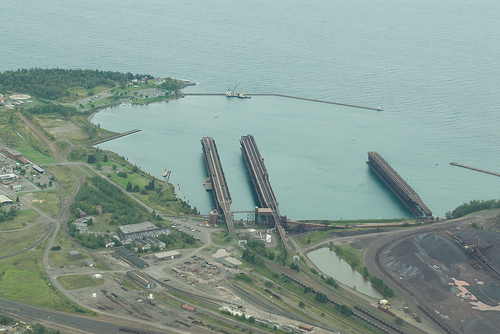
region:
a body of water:
[324, 156, 365, 190]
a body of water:
[286, 127, 311, 162]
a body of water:
[326, 41, 356, 68]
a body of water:
[255, 37, 283, 62]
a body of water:
[164, 22, 196, 53]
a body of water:
[122, 26, 141, 51]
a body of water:
[87, 28, 109, 48]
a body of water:
[50, 20, 78, 45]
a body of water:
[10, 25, 47, 57]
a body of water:
[463, 66, 493, 106]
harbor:
[190, 122, 281, 205]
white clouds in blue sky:
[415, 11, 446, 35]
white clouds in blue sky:
[294, 26, 325, 40]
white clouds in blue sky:
[352, 21, 390, 55]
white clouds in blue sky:
[182, 15, 219, 62]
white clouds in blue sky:
[11, 11, 45, 36]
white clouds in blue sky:
[31, 6, 66, 53]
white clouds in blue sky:
[78, 12, 116, 42]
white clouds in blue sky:
[132, 13, 173, 55]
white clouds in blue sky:
[170, 15, 210, 49]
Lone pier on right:
[357, 138, 435, 226]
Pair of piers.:
[194, 119, 287, 239]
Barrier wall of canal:
[184, 84, 391, 113]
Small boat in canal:
[218, 76, 256, 111]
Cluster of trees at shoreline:
[4, 56, 181, 107]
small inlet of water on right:
[303, 233, 390, 311]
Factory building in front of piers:
[111, 209, 184, 261]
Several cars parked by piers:
[166, 207, 219, 247]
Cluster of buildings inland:
[1, 140, 51, 230]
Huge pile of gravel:
[384, 225, 491, 328]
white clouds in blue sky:
[401, 6, 443, 46]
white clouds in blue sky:
[325, 25, 375, 75]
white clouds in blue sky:
[272, 6, 363, 48]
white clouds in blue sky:
[142, 22, 199, 44]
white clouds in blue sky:
[251, 22, 291, 69]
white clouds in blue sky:
[42, 6, 96, 24]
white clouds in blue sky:
[72, 11, 143, 59]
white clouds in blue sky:
[4, 5, 59, 43]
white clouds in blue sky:
[414, 25, 478, 92]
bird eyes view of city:
[0, 0, 496, 331]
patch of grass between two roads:
[0, 246, 60, 312]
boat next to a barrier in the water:
[220, 81, 252, 103]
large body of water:
[2, 2, 497, 119]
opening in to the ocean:
[370, 104, 492, 168]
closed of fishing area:
[87, 83, 487, 241]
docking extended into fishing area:
[358, 144, 436, 226]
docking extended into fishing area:
[237, 132, 282, 216]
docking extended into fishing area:
[194, 131, 234, 211]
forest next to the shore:
[3, 65, 148, 97]